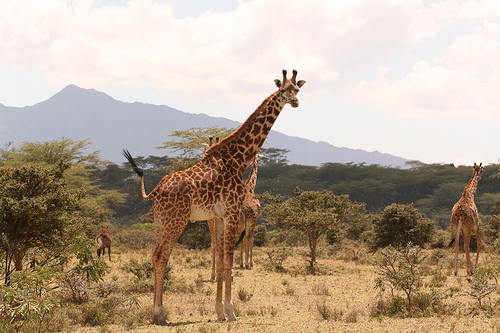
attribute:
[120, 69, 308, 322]
giraffe — here, present, brown, looking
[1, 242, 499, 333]
plain — here, sparse, sandy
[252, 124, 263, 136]
spot — brown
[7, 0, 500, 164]
cloud — white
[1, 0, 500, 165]
sky — overcast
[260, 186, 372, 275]
tree — brown, green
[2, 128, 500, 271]
trees — green, here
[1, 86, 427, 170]
mountain — here, present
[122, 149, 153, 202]
tail — black, up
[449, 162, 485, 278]
giraffe — walking, small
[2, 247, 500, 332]
grass — brown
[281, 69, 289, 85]
horn — black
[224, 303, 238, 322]
hoves — white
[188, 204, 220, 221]
belly — white